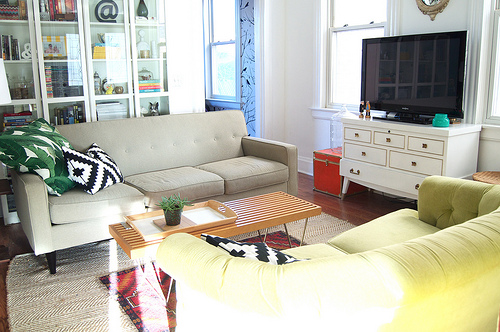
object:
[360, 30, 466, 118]
television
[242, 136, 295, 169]
arm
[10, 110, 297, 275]
couch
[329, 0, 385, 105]
window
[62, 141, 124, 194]
pillow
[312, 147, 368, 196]
red chest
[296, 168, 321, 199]
floor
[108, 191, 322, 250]
table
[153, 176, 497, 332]
couch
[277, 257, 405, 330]
light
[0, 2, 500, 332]
living room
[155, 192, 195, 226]
plant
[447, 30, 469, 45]
corner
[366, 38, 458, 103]
reflection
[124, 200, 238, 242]
tray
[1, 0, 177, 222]
bookshelf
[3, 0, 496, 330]
room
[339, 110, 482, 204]
drawers